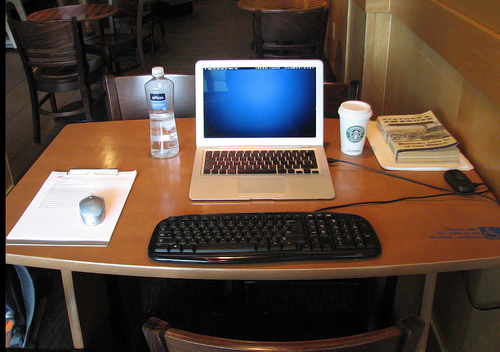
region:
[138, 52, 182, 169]
clear plastic water bottle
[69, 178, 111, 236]
silver wireless computer mouse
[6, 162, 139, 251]
clipboard with white paper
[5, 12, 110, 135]
brown wood dining room chair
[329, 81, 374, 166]
paper Starbucks coffee cup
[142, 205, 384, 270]
black computer keyboard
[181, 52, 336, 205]
white laptop computer with black keyboard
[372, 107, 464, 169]
book with black and white cover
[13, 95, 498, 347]
table in a coffee shop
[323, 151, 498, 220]
black computer power cords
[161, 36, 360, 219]
small white laptop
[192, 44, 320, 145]
bright blue screen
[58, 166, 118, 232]
silver mouse for computer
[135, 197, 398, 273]
rounded black key board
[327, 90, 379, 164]
cup of starbucks coffee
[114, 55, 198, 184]
tall clear bottle of water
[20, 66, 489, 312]
light brown wooden desk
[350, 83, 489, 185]
stack of papers and a book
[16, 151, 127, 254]
computer mouse on top of a notepad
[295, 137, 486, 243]
black cords for computer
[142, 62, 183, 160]
a plastic bottle on the table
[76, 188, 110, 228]
a mouse on the clip board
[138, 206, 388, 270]
a black plastic keyboard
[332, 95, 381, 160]
a white coffee cup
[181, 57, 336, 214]
a laptop in front of the keyboard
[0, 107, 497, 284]
a brown wooden table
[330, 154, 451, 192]
a black computer cord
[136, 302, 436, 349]
a brown wooden chair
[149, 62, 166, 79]
the lid of a water bottle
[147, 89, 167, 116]
a label on the bottle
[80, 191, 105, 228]
a silver wireless mouse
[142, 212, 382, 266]
a long black keyboard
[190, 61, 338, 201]
a small white laptop computer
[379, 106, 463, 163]
a large book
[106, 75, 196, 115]
part of a wooden chair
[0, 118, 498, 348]
a dark wooden table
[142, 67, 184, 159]
a plastic water bottle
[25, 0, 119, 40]
a small round table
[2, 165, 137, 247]
a gray and white pad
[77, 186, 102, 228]
mouse on a piece of paper.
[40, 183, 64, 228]
white piece of paper.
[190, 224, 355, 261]
black keyboard on desk.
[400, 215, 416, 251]
table made of wood.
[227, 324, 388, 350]
chair near the table.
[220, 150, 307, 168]
keyboard of the laptop.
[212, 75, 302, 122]
screen of the laptop.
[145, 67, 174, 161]
water bottle on table.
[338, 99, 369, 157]
white foam coffee cup.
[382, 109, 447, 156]
book on stack of paper.